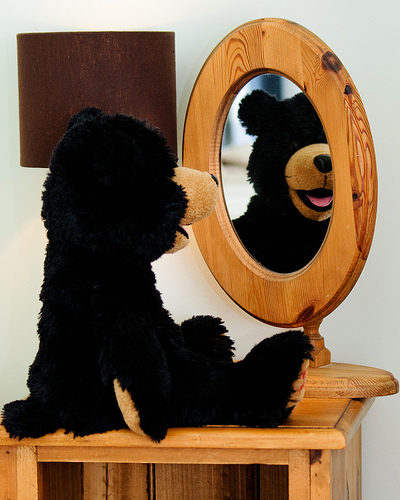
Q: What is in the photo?
A: A bear.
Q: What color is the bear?
A: Black.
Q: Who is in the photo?
A: No one.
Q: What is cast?
A: Reflection.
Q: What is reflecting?
A: Mirror.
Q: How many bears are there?
A: One.